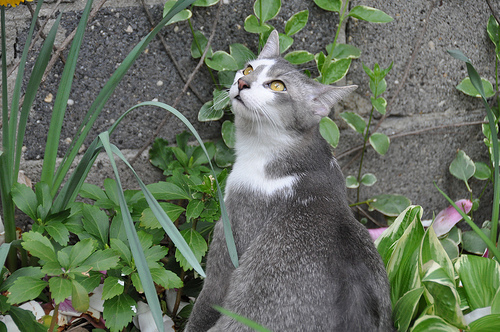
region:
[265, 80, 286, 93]
a golden cat eye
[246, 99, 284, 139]
white cat whiskers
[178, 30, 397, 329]
a gray cat looking up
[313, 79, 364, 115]
a cat ear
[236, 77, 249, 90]
a small cat nose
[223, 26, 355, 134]
the head of a cat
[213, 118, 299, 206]
a white patch on a gray cat's neck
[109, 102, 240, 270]
a blade of grass bending over onto a cat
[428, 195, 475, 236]
a pink bud beside a cat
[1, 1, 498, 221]
a concrete block wall behind a cat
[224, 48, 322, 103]
Yellow cat eyes with black stripe.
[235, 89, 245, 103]
Yellow cat eyes with black stripe.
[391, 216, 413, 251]
Yellow cat eyes with black stripe.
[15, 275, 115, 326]
Yellow cat eyes with black stripe.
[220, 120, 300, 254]
part of a neck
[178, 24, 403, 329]
gray cat with white chest staring upwards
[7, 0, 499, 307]
gray stone wall behind gray cat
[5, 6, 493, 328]
sunny outdoor clear daytime scene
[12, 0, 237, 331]
tall green grasses growing in garden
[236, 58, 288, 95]
golden eyes of cat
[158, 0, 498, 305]
ivy growing up sides of wall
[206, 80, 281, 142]
white whiskers of cat pointing downward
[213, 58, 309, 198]
white chest and face of cat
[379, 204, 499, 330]
green and white leaves of garden plants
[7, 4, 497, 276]
gray cinderblock wall behind cat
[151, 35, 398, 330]
a cat looking up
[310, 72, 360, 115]
the ear of a cat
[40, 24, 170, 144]
a brick wall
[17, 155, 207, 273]
green plants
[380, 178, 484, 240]
a purple flower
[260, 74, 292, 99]
the eye of a cat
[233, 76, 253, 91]
the nose of a cat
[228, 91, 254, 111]
the mouth of a cat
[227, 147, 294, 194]
white fur on a cat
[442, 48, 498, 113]
green leaves on a brick wall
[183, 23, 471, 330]
cat on the ground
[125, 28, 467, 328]
the cat is looking up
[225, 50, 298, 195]
white patch on cat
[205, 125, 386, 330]
the cat is gray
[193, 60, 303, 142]
whiskers on the cat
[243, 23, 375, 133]
ears on the cat